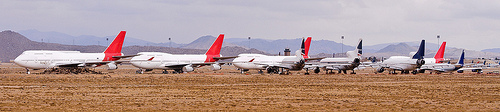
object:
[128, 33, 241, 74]
airplanes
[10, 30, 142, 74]
airplane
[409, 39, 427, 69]
tail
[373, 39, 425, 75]
airplane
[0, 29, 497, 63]
mountains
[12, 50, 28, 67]
nose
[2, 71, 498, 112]
ground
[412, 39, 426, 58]
tail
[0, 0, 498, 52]
sky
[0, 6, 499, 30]
clouds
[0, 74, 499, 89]
airstrip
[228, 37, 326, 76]
plane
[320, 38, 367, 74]
plane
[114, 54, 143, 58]
wing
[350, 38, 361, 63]
wing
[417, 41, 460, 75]
plane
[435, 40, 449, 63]
wing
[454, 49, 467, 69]
wing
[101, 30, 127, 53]
tail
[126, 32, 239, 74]
plane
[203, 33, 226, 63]
tail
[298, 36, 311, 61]
tail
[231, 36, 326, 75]
body